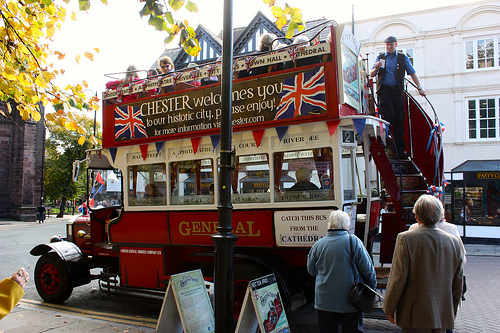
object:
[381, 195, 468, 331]
person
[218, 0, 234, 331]
pole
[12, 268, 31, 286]
hand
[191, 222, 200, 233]
letter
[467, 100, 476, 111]
window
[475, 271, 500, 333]
ground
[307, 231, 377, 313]
jumper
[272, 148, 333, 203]
window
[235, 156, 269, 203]
window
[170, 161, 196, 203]
window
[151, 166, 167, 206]
window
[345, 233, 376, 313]
purse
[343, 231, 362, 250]
shoulder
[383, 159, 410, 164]
stairs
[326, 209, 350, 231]
hair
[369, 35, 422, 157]
man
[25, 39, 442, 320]
bus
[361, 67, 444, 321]
stairwell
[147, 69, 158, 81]
passenger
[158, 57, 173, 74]
passenger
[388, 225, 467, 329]
brown jacket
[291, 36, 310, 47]
people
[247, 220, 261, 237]
l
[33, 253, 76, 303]
tire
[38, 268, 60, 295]
red hubcap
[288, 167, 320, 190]
man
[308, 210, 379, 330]
lady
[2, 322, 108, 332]
sidewalk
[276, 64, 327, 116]
flag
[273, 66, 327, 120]
british flag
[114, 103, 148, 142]
british flag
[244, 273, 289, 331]
sign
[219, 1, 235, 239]
pole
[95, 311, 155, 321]
lines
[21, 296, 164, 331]
curb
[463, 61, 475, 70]
window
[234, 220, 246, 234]
letter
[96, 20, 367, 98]
people sitting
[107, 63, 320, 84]
bus top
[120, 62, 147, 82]
person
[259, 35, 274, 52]
person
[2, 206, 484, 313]
road